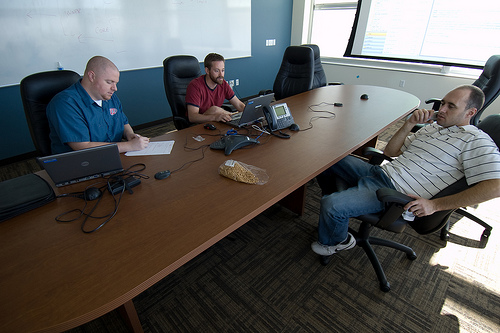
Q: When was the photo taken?
A: Daytime.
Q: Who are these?
A: Three men.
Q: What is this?
A: Table.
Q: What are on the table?
A: Telephone.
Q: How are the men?
A: Sitted.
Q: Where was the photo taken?
A: In a conference room.